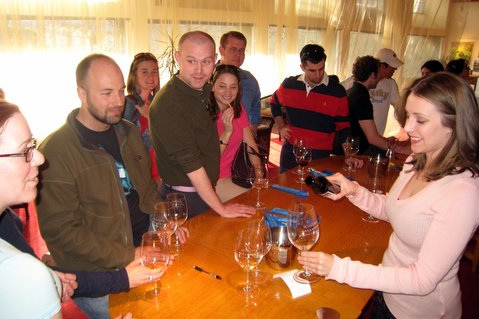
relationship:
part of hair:
[76, 72, 89, 90] [77, 54, 117, 89]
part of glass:
[294, 269, 322, 285] [286, 202, 320, 284]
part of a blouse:
[396, 182, 438, 250] [324, 156, 479, 316]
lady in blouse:
[298, 72, 479, 319] [324, 156, 479, 316]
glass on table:
[141, 231, 172, 306] [109, 141, 413, 318]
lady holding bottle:
[298, 72, 479, 319] [295, 169, 344, 198]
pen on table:
[193, 266, 223, 280] [109, 141, 413, 318]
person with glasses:
[0, 102, 77, 318] [1, 139, 39, 165]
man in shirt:
[270, 43, 365, 174] [270, 75, 352, 158]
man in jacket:
[36, 53, 189, 272] [35, 108, 170, 273]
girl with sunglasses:
[119, 51, 168, 229] [132, 51, 157, 60]